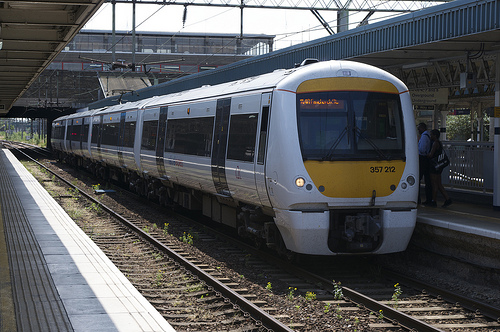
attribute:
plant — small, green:
[379, 277, 414, 308]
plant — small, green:
[322, 277, 347, 304]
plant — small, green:
[361, 300, 390, 328]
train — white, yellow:
[165, 59, 470, 309]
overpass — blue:
[67, 35, 279, 60]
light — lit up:
[295, 176, 304, 186]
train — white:
[50, 57, 417, 252]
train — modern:
[211, 83, 416, 246]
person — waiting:
[418, 127, 454, 211]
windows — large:
[162, 110, 264, 171]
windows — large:
[88, 110, 140, 147]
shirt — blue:
[422, 124, 432, 154]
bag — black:
[425, 157, 451, 174]